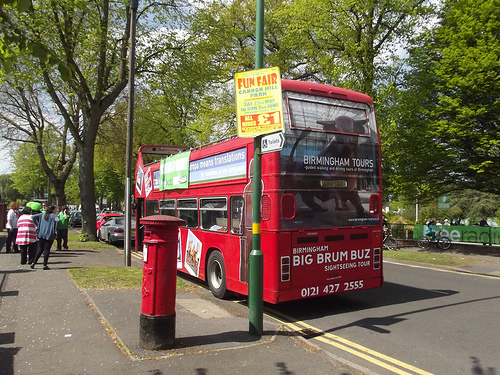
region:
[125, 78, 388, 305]
parked red bus on street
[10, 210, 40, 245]
red and white top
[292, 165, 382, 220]
windshield of red bus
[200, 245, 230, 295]
right wheel of red bus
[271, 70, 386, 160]
top setting area of red bus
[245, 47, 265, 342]
green pole on side of bus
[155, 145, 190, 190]
green and white banner on side of bus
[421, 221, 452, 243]
bike parked across the street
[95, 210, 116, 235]
parked red car on right side of street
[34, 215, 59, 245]
man wearing blue sweater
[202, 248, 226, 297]
wheels on a bus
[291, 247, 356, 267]
white letter on a red bus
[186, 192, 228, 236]
windows on a bus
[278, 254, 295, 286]
lights on a bus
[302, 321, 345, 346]
yellow lines on the oad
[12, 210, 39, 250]
white and pink striped sweater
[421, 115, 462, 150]
leaves in a tree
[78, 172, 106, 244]
a tree trunk by the road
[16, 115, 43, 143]
branches of a tree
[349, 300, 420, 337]
a shadow on the road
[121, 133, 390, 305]
The bus is a double decker bus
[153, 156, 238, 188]
The bus has advertisement all over it.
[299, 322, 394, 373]
Yellow lines on the edge of the street.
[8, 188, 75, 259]
People standing on the sidewalk.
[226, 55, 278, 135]
A poster sign posted to the pole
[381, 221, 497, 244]
People riding bicycles in the park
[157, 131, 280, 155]
The bus is empty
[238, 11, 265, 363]
The pole is green.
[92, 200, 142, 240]
Cars parked near the sidewalk.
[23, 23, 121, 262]
Tall green trees on the sidewalk.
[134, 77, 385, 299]
the bus is red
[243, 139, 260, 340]
the pole is green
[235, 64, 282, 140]
the sign is yellow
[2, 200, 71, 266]
people are standing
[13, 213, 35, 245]
the person has a striped shirt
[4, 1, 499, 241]
the trees are green and brown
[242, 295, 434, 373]
the street has a yellow line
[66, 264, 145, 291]
the grass is green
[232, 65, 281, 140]
the sign says "fun fair"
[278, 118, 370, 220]
the bus has an image of an animal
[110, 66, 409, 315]
a red doubledecker bus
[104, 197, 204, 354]
a red trash bin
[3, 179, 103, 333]
people on a sidewalk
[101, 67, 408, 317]
a large british bus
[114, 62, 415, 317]
a red tour bus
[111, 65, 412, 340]
a bus waiting for passengers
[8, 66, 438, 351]
people loading onto a bus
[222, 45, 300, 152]
an ad for fun fair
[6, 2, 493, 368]
a bus at a city street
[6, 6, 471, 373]
bus waiting at bus stop